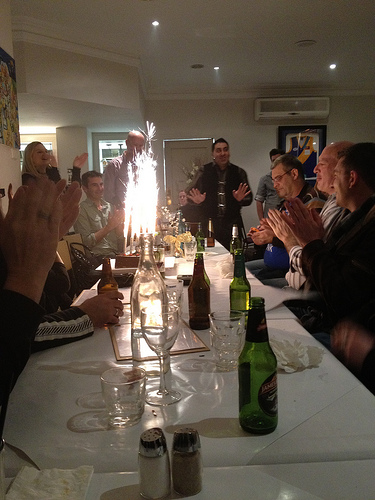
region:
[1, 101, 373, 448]
people at a party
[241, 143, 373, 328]
people clapping at a party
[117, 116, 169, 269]
sparklers on a cake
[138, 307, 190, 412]
a wine glass on a table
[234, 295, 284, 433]
a green glass bottle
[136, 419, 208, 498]
salt and pepper shakers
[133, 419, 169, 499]
salt shaker on a table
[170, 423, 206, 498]
pepper shaker on a table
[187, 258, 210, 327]
a brown glass bottle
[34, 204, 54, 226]
a ring on a finger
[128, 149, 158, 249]
Sparkling high candles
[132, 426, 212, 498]
Salt and pepper shaker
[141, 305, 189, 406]
Empty wine glass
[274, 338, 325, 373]
Wrinkled napkin at the end of table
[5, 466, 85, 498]
Nice folding napkin at end of table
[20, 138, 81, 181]
Blond woman standing clapping her hands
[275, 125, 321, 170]
Jersey in a large picture frame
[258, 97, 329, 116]
AC unit on the side of wall near ceiling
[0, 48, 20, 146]
Art picture on left hand side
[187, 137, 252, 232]
Man in vest holding up hands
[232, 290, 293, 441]
green bottle on white dining table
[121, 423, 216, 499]
salt and pepper shaker on dining table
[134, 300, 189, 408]
wine glass on table dining table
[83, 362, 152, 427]
short drinking glass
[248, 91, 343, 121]
wall air conditioner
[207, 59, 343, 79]
white ceiling lights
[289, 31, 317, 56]
round speaker in ceiling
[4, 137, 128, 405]
people clapping at long dining table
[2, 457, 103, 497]
paper square napkin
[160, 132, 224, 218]
framed painting on wall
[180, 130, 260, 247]
person at a dinner party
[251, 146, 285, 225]
person at a dinner party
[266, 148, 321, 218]
person at a dinner party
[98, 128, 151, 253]
person at a dinner party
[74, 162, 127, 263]
person at a dinner party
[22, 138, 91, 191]
person at a dinner party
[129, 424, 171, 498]
salt shaker on the table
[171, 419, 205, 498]
pepper shaker on the table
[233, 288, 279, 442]
glass bottle on the table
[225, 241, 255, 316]
glass bottle on the table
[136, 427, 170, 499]
A salt shaker on the table.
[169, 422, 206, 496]
A pepper shaker on the table.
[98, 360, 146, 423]
A glass cup on the table.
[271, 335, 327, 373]
A crumpled napkin on the table.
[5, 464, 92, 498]
A used napkin on the table.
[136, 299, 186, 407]
A wine glass on the table.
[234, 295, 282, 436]
A glass bottle on the table.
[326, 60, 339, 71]
A light on the ceiling.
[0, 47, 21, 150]
A painting on the wall.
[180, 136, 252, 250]
A man standing up.